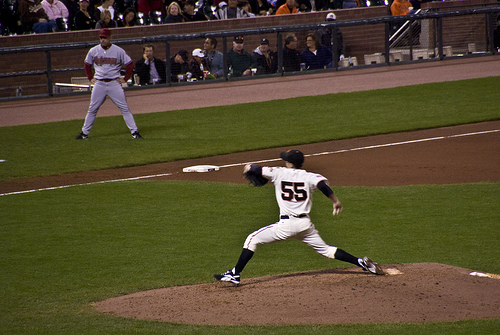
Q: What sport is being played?
A: Baseball.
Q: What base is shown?
A: Third base.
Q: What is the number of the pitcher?
A: 55.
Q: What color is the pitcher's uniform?
A: White.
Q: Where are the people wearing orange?
A: In the stands.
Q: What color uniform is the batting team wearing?
A: Grey with red lettering.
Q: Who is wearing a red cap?
A: The third base coach.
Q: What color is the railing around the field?
A: Black.